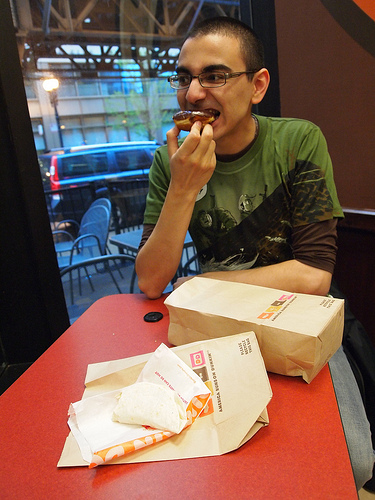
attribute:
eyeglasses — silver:
[165, 65, 250, 90]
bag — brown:
[161, 272, 345, 383]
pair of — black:
[173, 68, 233, 91]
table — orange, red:
[78, 318, 136, 354]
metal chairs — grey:
[69, 206, 109, 247]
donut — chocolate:
[165, 108, 227, 129]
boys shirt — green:
[235, 170, 312, 219]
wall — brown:
[293, 32, 373, 114]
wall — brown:
[272, 23, 362, 95]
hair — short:
[197, 20, 253, 44]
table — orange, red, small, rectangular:
[90, 316, 139, 344]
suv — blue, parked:
[77, 144, 163, 192]